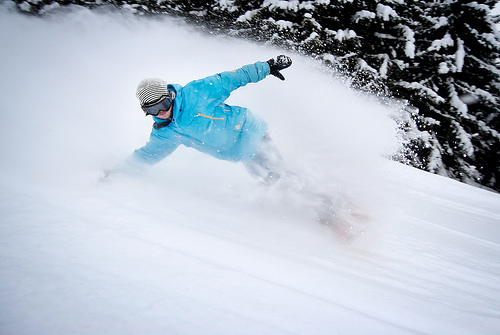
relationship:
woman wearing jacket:
[32, 0, 397, 267] [120, 90, 300, 178]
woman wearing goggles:
[32, 0, 397, 267] [140, 86, 179, 121]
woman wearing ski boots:
[32, 0, 397, 267] [305, 185, 366, 235]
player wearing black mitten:
[93, 57, 333, 211] [266, 51, 293, 80]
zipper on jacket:
[196, 112, 224, 121] [140, 50, 276, 202]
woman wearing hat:
[32, 0, 397, 267] [134, 75, 171, 103]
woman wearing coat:
[32, 0, 397, 267] [115, 63, 275, 173]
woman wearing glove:
[32, 0, 397, 267] [267, 55, 312, 75]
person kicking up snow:
[109, 57, 388, 255] [11, 35, 489, 322]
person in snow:
[109, 57, 388, 255] [130, 217, 199, 277]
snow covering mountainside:
[1, 126, 497, 333] [1, 42, 489, 332]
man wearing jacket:
[104, 49, 374, 241] [122, 54, 272, 172]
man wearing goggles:
[104, 49, 374, 241] [138, 94, 175, 117]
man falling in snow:
[104, 49, 374, 241] [361, 161, 499, 333]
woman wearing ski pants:
[86, 42, 323, 201] [230, 124, 364, 250]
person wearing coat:
[109, 57, 446, 280] [119, 73, 360, 178]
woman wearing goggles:
[86, 42, 323, 201] [138, 79, 179, 119]